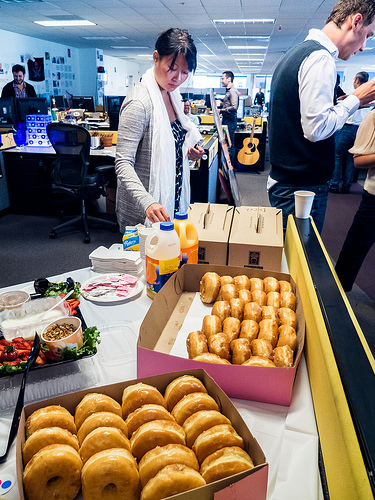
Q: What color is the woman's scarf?
A: White.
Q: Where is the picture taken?
A: Office.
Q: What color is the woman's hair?
A: Black.